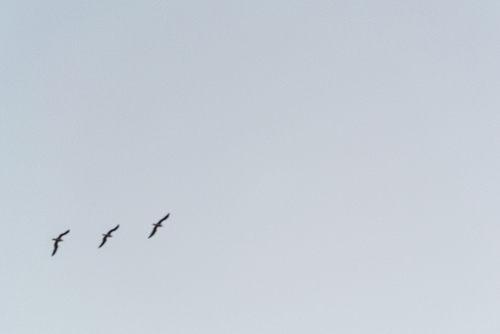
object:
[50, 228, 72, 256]
birds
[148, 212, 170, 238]
bird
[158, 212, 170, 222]
wing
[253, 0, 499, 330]
sky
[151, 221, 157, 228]
tail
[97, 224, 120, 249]
bird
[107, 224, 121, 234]
wing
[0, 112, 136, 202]
sky